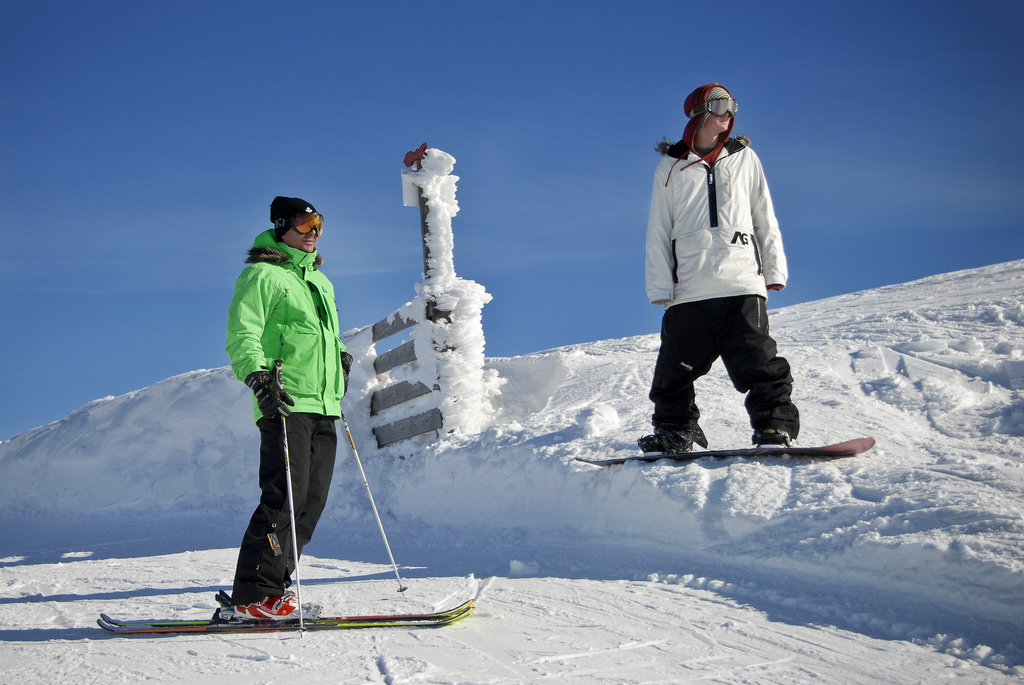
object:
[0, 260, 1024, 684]
ground